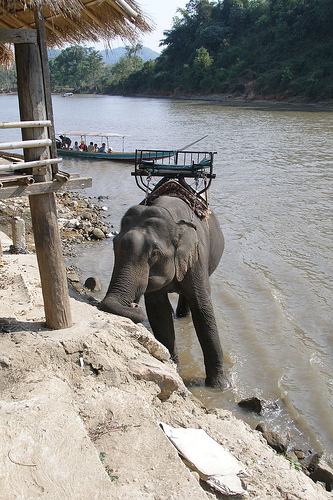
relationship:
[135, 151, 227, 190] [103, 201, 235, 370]
basket on elephant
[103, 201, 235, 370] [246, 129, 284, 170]
elephant in river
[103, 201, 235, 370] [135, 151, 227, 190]
elephant has basket